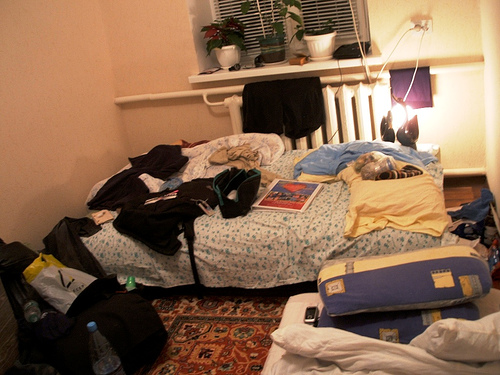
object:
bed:
[78, 144, 446, 296]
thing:
[207, 143, 286, 189]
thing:
[112, 182, 219, 300]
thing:
[212, 167, 262, 219]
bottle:
[125, 275, 136, 292]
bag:
[78, 272, 169, 375]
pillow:
[334, 160, 450, 238]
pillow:
[317, 302, 480, 345]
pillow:
[316, 245, 491, 318]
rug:
[172, 294, 259, 371]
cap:
[87, 321, 98, 332]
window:
[209, 0, 367, 66]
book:
[250, 178, 324, 213]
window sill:
[188, 52, 386, 85]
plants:
[196, 0, 336, 58]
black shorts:
[240, 76, 326, 140]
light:
[386, 100, 407, 132]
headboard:
[222, 81, 409, 153]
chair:
[259, 287, 500, 375]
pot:
[212, 44, 241, 70]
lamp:
[370, 80, 392, 141]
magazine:
[250, 178, 325, 213]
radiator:
[201, 78, 391, 153]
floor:
[160, 302, 263, 375]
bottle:
[85, 321, 123, 371]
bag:
[212, 166, 261, 219]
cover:
[251, 178, 324, 213]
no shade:
[388, 74, 429, 145]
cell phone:
[303, 302, 319, 324]